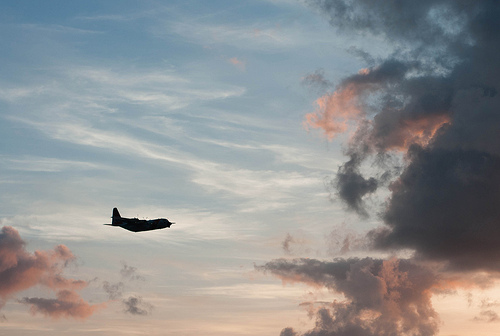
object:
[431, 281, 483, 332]
hue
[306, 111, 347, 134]
sun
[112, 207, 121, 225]
tail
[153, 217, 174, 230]
head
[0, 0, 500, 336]
night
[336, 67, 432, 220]
sunset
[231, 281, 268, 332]
sunlight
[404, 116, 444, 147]
sun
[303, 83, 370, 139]
hue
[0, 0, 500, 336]
cloud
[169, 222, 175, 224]
wing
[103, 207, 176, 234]
airplane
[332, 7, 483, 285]
storm cloud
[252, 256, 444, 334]
storm cloud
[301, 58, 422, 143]
storm cloud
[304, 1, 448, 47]
storm cloud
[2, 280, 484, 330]
sunset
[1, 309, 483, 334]
horizon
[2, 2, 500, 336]
sky